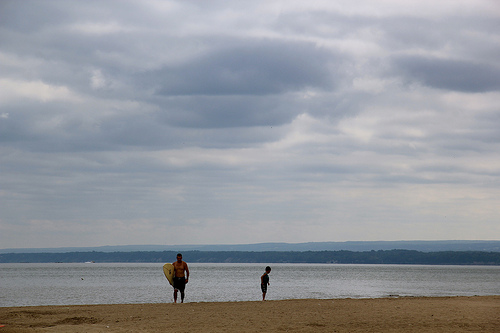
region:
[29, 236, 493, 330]
this is a beach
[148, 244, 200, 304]
this is a man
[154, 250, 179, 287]
this is a surfboard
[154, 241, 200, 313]
a man holding a surfboard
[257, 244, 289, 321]
this is a kid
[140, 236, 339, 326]
two people at the beach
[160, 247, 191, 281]
man without a shirt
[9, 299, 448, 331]
multiple tracks in the sand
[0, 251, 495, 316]
the water is calm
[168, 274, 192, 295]
a man wearing shorts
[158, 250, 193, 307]
Man with a surfboard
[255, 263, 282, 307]
young boy on the beach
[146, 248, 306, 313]
young boy and man on deserted beach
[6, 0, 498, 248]
Dark clouds fill the sky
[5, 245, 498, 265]
Trees on the horizon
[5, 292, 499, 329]
Beach in front of the water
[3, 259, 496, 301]
Greenish water after the beach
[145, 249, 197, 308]
Man in dark swim trunks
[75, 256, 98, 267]
Boat in the distance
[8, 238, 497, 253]
hills on the horizon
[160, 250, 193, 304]
Man carrying a yellow surfboard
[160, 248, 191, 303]
Man standing on a beach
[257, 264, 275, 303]
Boy standing on a beach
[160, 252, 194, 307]
Man with a tank top tan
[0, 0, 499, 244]
Gray storm clouds in the sky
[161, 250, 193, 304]
Man wearing swim shorts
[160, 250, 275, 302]
Man and a boy on a beach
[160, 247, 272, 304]
Two people on a beach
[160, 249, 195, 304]
Man walking out of an ocean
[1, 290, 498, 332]
Brown sand beach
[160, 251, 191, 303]
a man holding a surfboard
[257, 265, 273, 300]
a little boy standing near the water on a beach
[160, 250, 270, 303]
a father and son at the beach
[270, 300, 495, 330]
brown sand on the beach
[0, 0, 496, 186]
clouds in the sky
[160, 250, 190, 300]
a man walking out of the water on a beach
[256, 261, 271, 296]
a young boy standing beside the water on the beach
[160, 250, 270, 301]
a young boy and man at the beach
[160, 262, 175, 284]
the front of a surfboard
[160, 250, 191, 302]
a surfer holding a surfboard with the right hand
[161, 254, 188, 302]
A man standing on the sand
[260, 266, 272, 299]
A child by the water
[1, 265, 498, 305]
A body of water behind the man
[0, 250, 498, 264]
Trees across the water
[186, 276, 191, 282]
The left hand of the man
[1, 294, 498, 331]
Sand at the beach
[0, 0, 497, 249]
The sky above the water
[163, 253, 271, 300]
Two people standing at the beach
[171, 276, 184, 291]
The man is wearing shorts